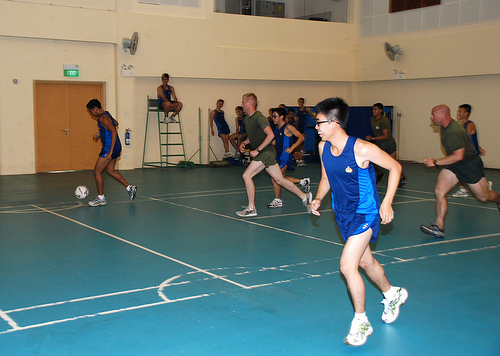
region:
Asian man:
[301, 103, 421, 331]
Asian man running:
[302, 80, 453, 350]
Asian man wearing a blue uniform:
[280, 89, 424, 354]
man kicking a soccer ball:
[75, 98, 151, 250]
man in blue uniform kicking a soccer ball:
[61, 96, 159, 284]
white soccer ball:
[63, 181, 94, 207]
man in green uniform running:
[214, 91, 306, 228]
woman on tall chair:
[136, 65, 188, 161]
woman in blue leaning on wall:
[199, 88, 231, 188]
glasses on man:
[314, 92, 365, 169]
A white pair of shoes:
[341, 283, 416, 349]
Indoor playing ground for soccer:
[2, 142, 499, 351]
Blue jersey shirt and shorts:
[312, 131, 386, 256]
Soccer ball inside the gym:
[72, 183, 95, 199]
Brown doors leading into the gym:
[29, 75, 122, 177]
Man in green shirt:
[241, 111, 281, 174]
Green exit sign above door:
[60, 61, 87, 79]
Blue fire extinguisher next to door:
[122, 126, 135, 147]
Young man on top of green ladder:
[138, 70, 195, 172]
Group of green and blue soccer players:
[67, 91, 496, 338]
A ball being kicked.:
[50, 172, 102, 222]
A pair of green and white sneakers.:
[334, 264, 429, 354]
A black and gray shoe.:
[390, 213, 452, 253]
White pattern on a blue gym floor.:
[17, 245, 270, 335]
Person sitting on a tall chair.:
[142, 63, 196, 206]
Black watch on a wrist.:
[402, 149, 444, 192]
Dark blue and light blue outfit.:
[262, 140, 374, 302]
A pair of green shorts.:
[227, 142, 291, 182]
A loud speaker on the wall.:
[342, 28, 408, 96]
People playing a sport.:
[72, 73, 472, 239]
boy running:
[296, 110, 434, 353]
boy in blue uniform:
[306, 90, 413, 355]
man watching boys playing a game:
[146, 72, 203, 167]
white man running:
[409, 92, 499, 242]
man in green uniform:
[239, 91, 314, 222]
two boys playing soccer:
[221, 96, 315, 213]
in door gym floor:
[52, 252, 155, 353]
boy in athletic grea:
[311, 97, 424, 353]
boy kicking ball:
[66, 102, 158, 211]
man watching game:
[206, 100, 243, 164]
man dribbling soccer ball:
[65, 80, 168, 230]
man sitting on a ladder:
[141, 51, 207, 171]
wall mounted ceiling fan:
[368, 26, 419, 77]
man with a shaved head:
[423, 98, 493, 255]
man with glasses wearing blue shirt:
[297, 80, 394, 245]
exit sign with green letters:
[55, 62, 83, 78]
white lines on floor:
[137, 231, 254, 317]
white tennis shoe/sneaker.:
[341, 303, 381, 346]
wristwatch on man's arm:
[425, 145, 443, 175]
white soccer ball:
[63, 174, 90, 207]